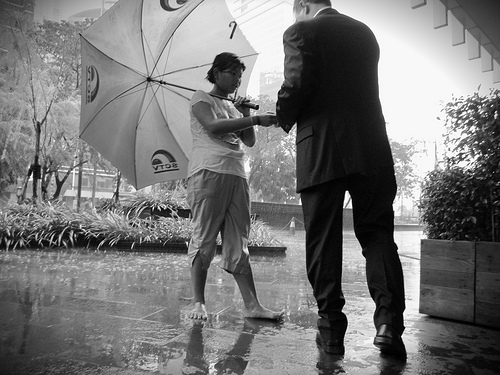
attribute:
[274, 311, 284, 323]
toe — white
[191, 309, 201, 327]
toe — white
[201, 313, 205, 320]
toe — white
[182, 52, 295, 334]
human — white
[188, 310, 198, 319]
toe — white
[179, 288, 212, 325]
foot — white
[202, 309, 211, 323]
toe — white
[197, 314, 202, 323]
toe — white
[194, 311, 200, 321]
toe — white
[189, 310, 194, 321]
toe — white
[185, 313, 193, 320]
toe — white